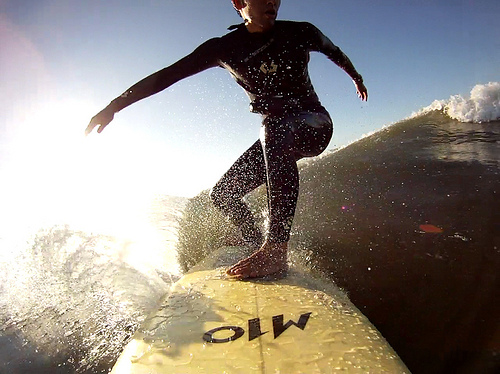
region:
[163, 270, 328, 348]
"Mlo" is on the surfboard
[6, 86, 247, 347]
Water is splashing on to the surfboard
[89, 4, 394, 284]
He is wearing a wet suit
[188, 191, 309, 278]
he is barefooted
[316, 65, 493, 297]
The water is dark blue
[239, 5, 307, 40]
His mouth is open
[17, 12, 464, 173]
It's sunny here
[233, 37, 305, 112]
There is a logo on the suit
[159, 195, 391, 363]
The surfboard is white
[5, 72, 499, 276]
He is riding a wave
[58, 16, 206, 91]
the sky is clear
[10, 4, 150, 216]
sun's glare is white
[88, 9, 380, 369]
a person is surfing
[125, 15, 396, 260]
person is wearing wet suit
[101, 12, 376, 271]
the wet suit is black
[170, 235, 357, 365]
the text is black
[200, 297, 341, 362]
the text is M10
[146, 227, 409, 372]
the surfboard is white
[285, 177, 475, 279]
the water is dirty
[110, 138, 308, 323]
A surfer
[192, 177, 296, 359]
A surfer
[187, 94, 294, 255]
A surfer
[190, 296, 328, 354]
M10 upside down in black text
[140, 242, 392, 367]
white surfboard with black text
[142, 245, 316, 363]
wet white surfboard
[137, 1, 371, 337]
boy wearing black wetsuit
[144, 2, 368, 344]
man surfing on white surfboard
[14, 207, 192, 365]
white sea foam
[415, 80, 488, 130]
grey sea water and sea foam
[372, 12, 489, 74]
blue sky with no clouds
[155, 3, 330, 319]
man wearing wetsuit surfing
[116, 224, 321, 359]
white surfboard on ocean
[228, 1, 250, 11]
Left ear on man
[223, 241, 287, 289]
Man's bare foot on board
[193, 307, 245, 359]
Letter o in black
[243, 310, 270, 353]
Number one in black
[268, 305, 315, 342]
Letter m in black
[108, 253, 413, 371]
Yellow board in ocean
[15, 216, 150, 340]
Water splashing in ocean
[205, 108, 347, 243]
Man wearing black pants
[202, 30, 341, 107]
Man wearing black top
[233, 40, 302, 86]
White design on black shirt